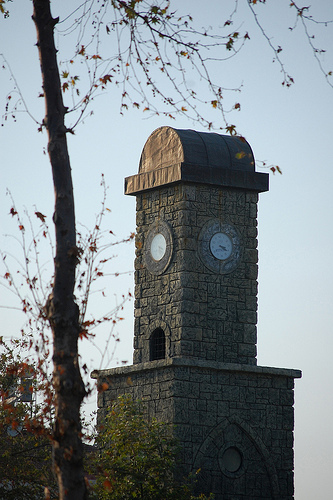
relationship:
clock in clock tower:
[207, 233, 233, 262] [83, 117, 305, 497]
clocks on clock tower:
[140, 216, 236, 269] [83, 117, 305, 497]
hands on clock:
[215, 239, 228, 253] [207, 233, 233, 262]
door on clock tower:
[145, 321, 173, 361] [83, 117, 305, 497]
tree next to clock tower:
[18, 6, 104, 499] [83, 117, 305, 497]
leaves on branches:
[75, 45, 122, 96] [55, 3, 270, 132]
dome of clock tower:
[117, 119, 274, 196] [83, 117, 305, 497]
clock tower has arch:
[83, 117, 305, 497] [187, 411, 283, 499]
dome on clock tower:
[117, 119, 274, 196] [83, 117, 305, 497]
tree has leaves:
[18, 6, 104, 499] [75, 45, 122, 96]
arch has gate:
[187, 411, 283, 499] [210, 469, 252, 499]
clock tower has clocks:
[83, 117, 305, 497] [140, 216, 236, 269]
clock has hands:
[207, 233, 233, 262] [215, 239, 228, 253]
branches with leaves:
[55, 3, 270, 132] [75, 45, 122, 96]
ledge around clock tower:
[90, 354, 305, 390] [83, 117, 305, 497]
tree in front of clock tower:
[18, 6, 104, 499] [83, 117, 305, 497]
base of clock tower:
[90, 354, 314, 499] [83, 117, 305, 497]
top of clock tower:
[122, 118, 272, 364] [83, 117, 305, 497]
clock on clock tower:
[207, 233, 233, 262] [83, 117, 305, 497]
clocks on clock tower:
[149, 233, 167, 261] [83, 117, 305, 497]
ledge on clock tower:
[90, 354, 305, 390] [83, 117, 305, 497]